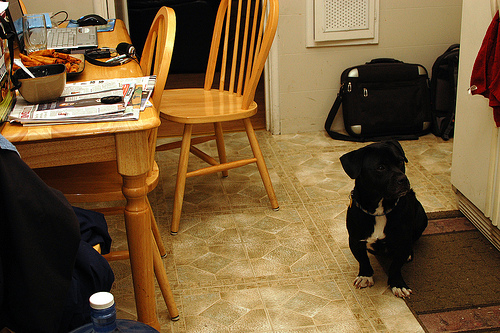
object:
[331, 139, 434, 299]
dog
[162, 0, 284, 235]
chair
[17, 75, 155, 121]
magazines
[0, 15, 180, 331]
table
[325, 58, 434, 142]
bag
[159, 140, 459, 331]
floor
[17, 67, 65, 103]
bowl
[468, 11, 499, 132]
clothing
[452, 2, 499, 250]
wall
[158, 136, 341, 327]
tiles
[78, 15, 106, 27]
mouse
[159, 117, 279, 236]
legs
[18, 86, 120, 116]
newspaper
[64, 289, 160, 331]
jug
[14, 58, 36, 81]
spoon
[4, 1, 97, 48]
laptop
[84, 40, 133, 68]
headphones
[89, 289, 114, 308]
lid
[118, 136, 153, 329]
leg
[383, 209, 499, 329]
carpet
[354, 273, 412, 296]
paws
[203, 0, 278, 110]
back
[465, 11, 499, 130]
towel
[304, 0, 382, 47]
vent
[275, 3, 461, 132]
wall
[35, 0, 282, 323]
chairs